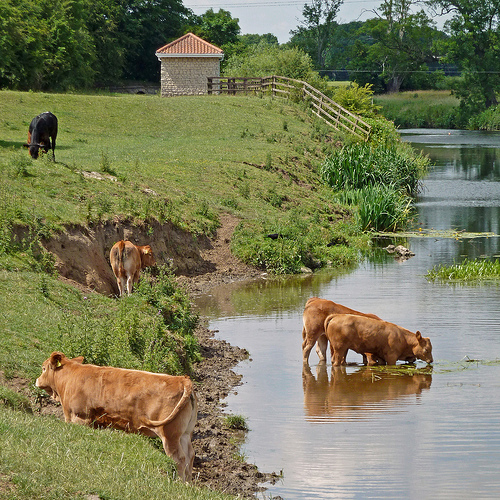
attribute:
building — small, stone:
[152, 33, 223, 90]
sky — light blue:
[245, 10, 285, 23]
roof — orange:
[142, 41, 244, 77]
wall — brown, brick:
[160, 59, 219, 94]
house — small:
[154, 34, 224, 95]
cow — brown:
[34, 350, 199, 480]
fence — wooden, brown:
[206, 76, 371, 143]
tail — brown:
[144, 381, 193, 429]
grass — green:
[424, 256, 499, 287]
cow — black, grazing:
[18, 107, 68, 168]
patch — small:
[376, 420, 438, 471]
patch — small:
[174, 138, 198, 164]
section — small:
[230, 81, 256, 90]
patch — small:
[251, 12, 274, 30]